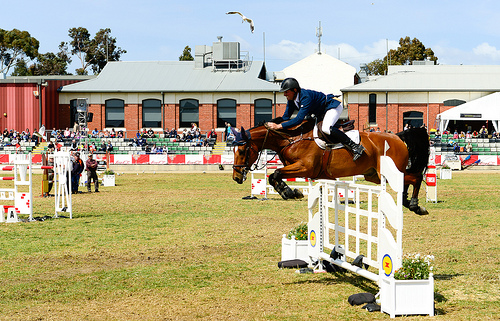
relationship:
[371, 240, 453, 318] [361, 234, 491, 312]
planter with flowers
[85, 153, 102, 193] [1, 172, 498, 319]
person on field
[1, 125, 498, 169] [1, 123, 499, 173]
seating for spectators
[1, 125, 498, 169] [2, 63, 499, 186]
seating in arena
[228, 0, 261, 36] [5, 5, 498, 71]
seabird in air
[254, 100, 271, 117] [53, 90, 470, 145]
window on building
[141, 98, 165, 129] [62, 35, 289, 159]
window on building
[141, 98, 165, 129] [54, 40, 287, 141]
window on building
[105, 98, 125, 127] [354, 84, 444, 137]
window on building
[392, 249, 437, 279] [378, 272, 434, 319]
flowers in planter